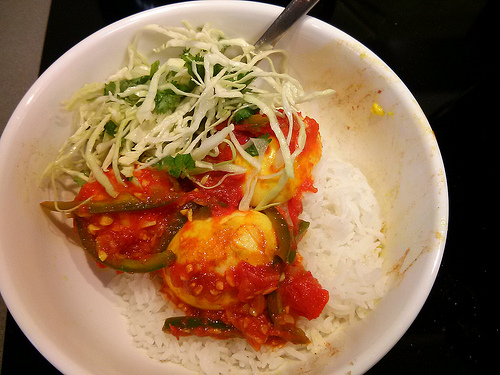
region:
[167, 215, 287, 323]
this is an egg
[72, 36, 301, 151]
these are some vegetables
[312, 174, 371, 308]
this is white rice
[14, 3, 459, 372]
this is a white plate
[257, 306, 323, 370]
this is tomato paste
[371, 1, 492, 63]
this is a black mat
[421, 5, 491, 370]
this is a black mat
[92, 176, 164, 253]
this is smashed tomato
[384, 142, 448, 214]
the plate is white in color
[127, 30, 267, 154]
the cabbages are sliced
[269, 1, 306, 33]
this is a spoon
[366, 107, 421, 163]
the plate is round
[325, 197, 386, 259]
the plate is white in color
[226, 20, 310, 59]
Silver utensil on side of bowl.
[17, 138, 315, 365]
Bowl is white in color.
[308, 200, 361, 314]
White rice on bottom of bowl.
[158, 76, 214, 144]
White cabbage in bowl.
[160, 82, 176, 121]
Green cilantro in bowl.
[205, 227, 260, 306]
Yellow squash in bowl.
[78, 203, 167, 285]
Green pepper in bowl.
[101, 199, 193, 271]
Red sauce on food in bowl.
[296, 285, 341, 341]
Red sauce in food in bowl.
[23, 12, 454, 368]
this is a dinner food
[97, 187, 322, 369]
the sauce on the food is red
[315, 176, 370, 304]
this is sticky rice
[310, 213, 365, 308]
the rice is white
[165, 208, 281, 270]
this vegetable is yellow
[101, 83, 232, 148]
this vegetable is light green and dark green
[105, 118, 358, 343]
food in the bowl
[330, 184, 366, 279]
the rice is white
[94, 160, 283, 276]
sauce on the food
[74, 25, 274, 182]
vegetables in the corner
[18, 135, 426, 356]
the bowl is round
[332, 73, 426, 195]
sauce on the bowl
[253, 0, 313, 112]
fork in the bowl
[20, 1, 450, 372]
A bowl of food.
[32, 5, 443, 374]
A white round bowl.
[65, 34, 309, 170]
Shredded lettuce.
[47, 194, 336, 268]
Slices of cooked green peppers.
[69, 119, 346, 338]
Food with a red sauce.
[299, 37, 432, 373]
food residue on the side of the bowl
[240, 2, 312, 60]
silver metal utensil in bowl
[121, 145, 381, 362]
white rice on bottom of bowl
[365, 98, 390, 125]
yellow corn kernel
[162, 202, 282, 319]
yellow cut tomato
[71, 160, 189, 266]
red cut tomato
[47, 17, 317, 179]
shredded green lettuce on top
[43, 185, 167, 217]
cut green pepper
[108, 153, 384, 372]
the rice is white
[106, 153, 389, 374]
the rice is in a pile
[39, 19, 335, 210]
the vegetables are shredded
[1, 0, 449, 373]
the food in the bowl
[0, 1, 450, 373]
the bowl is white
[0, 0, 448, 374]
the utensil in the bowl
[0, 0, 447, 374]
the red sauce in the bowl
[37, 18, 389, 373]
the shredded vegetable next to the rice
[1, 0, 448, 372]
the food is in the bowl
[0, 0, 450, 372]
the white bowl is filled with food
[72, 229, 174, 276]
The piece of pepper on the plate is green.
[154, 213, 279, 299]
The tomato sauce on the plate is red.